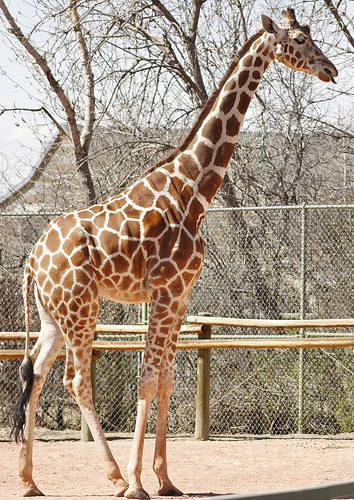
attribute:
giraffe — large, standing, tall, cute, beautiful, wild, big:
[7, 3, 338, 499]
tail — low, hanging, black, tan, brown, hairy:
[6, 267, 41, 449]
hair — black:
[5, 356, 40, 447]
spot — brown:
[113, 271, 140, 294]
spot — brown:
[125, 279, 144, 296]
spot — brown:
[100, 277, 119, 293]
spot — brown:
[118, 289, 134, 304]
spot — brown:
[98, 258, 117, 280]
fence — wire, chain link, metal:
[1, 200, 354, 444]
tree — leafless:
[1, 2, 138, 431]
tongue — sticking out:
[326, 69, 342, 88]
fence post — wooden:
[191, 307, 221, 443]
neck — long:
[154, 22, 282, 230]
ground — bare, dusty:
[2, 431, 353, 500]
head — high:
[258, 4, 343, 90]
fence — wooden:
[1, 309, 353, 445]